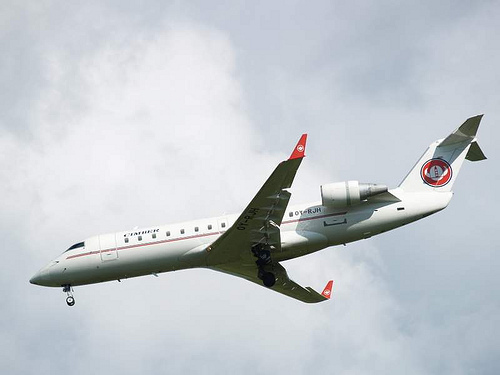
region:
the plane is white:
[17, 107, 482, 326]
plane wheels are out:
[31, 236, 315, 319]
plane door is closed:
[94, 223, 130, 275]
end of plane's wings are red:
[276, 123, 343, 328]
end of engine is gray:
[342, 171, 380, 211]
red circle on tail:
[417, 156, 457, 196]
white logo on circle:
[426, 158, 451, 186]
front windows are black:
[62, 238, 88, 258]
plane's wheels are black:
[241, 239, 289, 306]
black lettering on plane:
[287, 198, 329, 225]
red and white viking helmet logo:
[416, 154, 456, 188]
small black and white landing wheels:
[57, 287, 83, 312]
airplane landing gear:
[54, 289, 85, 312]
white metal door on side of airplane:
[93, 231, 121, 263]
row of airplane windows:
[120, 220, 235, 245]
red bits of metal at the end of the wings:
[280, 123, 320, 163]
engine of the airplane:
[311, 174, 396, 214]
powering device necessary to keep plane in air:
[315, 175, 390, 217]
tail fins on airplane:
[443, 109, 493, 172]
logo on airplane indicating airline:
[117, 225, 164, 239]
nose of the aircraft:
[24, 227, 200, 343]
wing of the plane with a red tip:
[226, 117, 324, 235]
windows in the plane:
[107, 213, 221, 248]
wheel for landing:
[56, 277, 96, 344]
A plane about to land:
[23, 137, 473, 337]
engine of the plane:
[306, 170, 428, 225]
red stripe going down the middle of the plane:
[56, 208, 363, 239]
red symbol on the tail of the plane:
[396, 139, 472, 197]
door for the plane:
[61, 198, 151, 286]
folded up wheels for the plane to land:
[233, 227, 298, 299]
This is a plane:
[21, 95, 490, 326]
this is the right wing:
[189, 115, 316, 247]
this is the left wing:
[216, 243, 371, 338]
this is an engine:
[316, 172, 393, 212]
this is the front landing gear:
[58, 280, 85, 310]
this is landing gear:
[225, 225, 292, 303]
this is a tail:
[373, 99, 497, 221]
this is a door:
[96, 227, 125, 272]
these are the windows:
[102, 196, 234, 256]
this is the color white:
[182, 320, 189, 342]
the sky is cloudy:
[50, 64, 177, 171]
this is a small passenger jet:
[25, 54, 493, 336]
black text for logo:
[106, 200, 178, 284]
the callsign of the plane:
[262, 189, 341, 251]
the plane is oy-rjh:
[220, 165, 285, 260]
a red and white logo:
[372, 139, 468, 221]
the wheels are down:
[10, 151, 321, 355]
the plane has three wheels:
[28, 190, 291, 332]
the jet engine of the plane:
[306, 177, 399, 232]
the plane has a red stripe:
[6, 176, 466, 305]